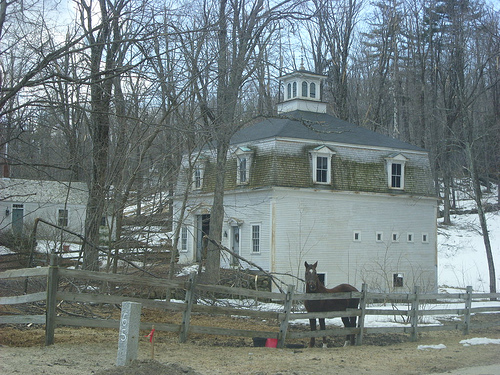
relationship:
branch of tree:
[76, 142, 148, 208] [38, 5, 451, 202]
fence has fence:
[0, 250, 498, 349] [0, 250, 498, 349]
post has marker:
[143, 323, 162, 362] [144, 323, 156, 341]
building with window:
[169, 50, 441, 306] [389, 161, 401, 187]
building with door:
[169, 50, 441, 306] [229, 225, 240, 265]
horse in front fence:
[299, 261, 363, 350] [1, 252, 499, 346]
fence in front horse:
[1, 252, 499, 346] [299, 261, 363, 350]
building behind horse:
[169, 50, 441, 306] [299, 261, 363, 350]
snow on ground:
[0, 174, 498, 351] [0, 172, 499, 373]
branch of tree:
[87, 1, 119, 115] [1, 0, 236, 229]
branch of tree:
[236, 1, 264, 41] [171, 3, 289, 284]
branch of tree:
[216, 3, 226, 103] [171, 3, 289, 284]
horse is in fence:
[302, 261, 362, 345] [1, 252, 499, 346]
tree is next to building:
[39, 0, 141, 274] [169, 50, 441, 306]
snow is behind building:
[81, 169, 498, 316] [169, 50, 441, 306]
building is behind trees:
[1, 169, 93, 248] [3, 1, 155, 264]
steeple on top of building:
[272, 45, 329, 115] [169, 50, 441, 306]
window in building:
[383, 150, 409, 190] [169, 50, 441, 306]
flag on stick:
[133, 314, 183, 358] [233, 287, 286, 357]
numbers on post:
[105, 290, 157, 372] [115, 300, 141, 369]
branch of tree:
[0, 23, 104, 107] [29, 25, 261, 307]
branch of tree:
[2, 5, 147, 114] [168, 22, 265, 132]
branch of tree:
[41, 78, 67, 130] [62, 2, 125, 273]